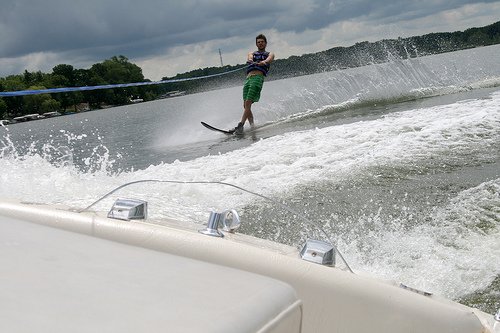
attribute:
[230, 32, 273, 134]
skier — white, tall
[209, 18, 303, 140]
man — skiing, white, tall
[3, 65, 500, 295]
water — dark, brown, big, grey, deep, wild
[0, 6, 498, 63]
sky — dark, grey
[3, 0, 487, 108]
trees — green, wide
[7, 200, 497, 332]
boat — white, big, wide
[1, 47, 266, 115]
rope — blue, long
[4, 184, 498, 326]
boat — white